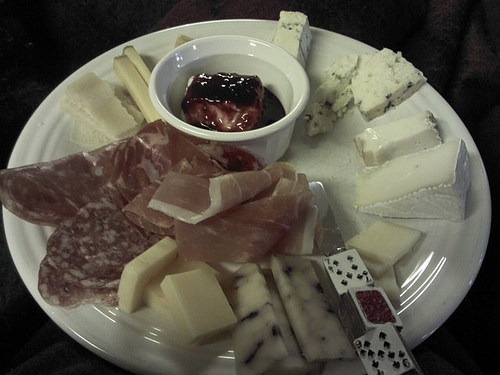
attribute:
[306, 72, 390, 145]
cheese — brie, next, spread, small, wedged, yellow, white, here, dark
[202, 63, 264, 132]
sauces — dipping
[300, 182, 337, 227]
knife — spreader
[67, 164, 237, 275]
salami — sliced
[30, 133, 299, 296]
meats — various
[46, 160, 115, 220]
meat — thin, spotted, ham, here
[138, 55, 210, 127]
bowl — ceramic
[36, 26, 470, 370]
plate — round, white, appetizing, here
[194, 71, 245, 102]
sauce — purple, barbeque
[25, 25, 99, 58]
tablecloth — black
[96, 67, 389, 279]
food — here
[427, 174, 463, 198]
cake — here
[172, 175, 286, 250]
ham — here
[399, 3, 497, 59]
cloth — here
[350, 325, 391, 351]
card — here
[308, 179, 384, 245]
blade — here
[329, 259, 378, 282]
spades — seven, nine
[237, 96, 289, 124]
jelly — covering